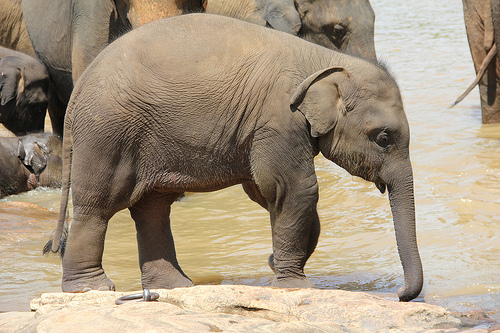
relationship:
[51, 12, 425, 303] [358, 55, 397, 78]
elephant has hair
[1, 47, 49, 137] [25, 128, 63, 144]
elephant has short hair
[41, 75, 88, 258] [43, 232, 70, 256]
tail has hair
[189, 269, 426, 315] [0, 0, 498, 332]
shadow in water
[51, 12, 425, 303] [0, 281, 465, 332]
elephant standing on rock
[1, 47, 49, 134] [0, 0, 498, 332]
baby elephant in river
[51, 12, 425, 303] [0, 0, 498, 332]
elephant slurping water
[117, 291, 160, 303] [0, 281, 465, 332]
excrement on rock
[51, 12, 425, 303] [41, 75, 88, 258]
elephant has tail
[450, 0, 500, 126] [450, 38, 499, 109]
elephant has tail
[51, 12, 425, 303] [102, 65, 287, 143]
elephant has wrinkled skin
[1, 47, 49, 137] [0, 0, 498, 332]
elephant swimming in river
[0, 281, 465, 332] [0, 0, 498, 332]
rock in water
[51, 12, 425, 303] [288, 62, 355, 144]
elephant has large ear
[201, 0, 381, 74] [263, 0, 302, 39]
elephant has large ear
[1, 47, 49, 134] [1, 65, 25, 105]
elephant has large ear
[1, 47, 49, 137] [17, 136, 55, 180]
elephant has large ear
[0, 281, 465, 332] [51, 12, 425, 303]
rock in front of elephant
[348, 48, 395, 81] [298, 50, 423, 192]
hair on head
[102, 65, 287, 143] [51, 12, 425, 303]
wrinkles on body